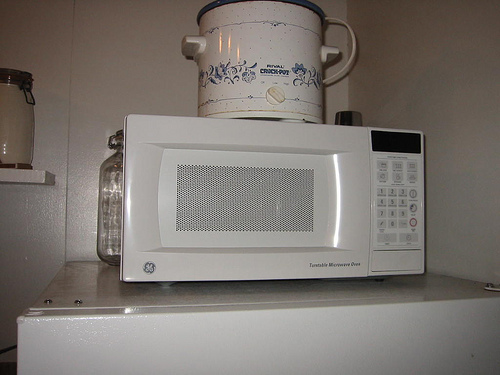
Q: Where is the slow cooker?
A: On top of the microwave.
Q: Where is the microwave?
A: On top of the refrigerator.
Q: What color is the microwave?
A: White.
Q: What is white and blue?
A: The crock pot.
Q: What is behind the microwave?
A: A glass jar.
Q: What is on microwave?
A: Crockpot.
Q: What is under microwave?
A: Top of fridge.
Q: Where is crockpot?
A: Sitting on microwave.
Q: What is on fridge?
A: Microwave.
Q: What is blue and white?
A: Crockpot on microwave.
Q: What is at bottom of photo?
A: Top of fridge.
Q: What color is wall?
A: White.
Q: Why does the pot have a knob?
A: Temperature control.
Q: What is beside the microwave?
A: A mason jar.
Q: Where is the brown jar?
A: On the shelf.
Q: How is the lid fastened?
A: With a clasp.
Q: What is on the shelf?
A: A jar.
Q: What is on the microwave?
A: A slow cooker.